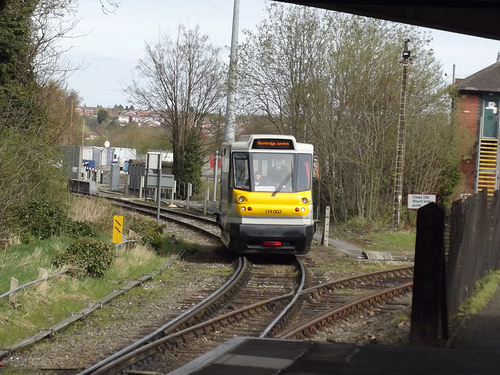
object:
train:
[215, 134, 317, 259]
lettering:
[257, 140, 289, 146]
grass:
[315, 257, 356, 275]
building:
[80, 144, 139, 175]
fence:
[386, 196, 498, 355]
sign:
[408, 194, 436, 210]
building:
[442, 64, 500, 179]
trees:
[254, 14, 417, 209]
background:
[72, 52, 336, 190]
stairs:
[473, 135, 497, 207]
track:
[201, 171, 291, 372]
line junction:
[217, 282, 332, 341]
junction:
[162, 256, 295, 360]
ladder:
[390, 40, 415, 228]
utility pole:
[393, 58, 407, 226]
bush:
[429, 168, 461, 198]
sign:
[257, 141, 290, 146]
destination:
[257, 141, 289, 146]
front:
[234, 182, 324, 220]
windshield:
[234, 153, 313, 198]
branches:
[246, 4, 333, 123]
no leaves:
[257, 26, 297, 56]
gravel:
[307, 259, 347, 279]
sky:
[78, 27, 149, 69]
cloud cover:
[73, 14, 191, 35]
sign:
[112, 215, 123, 244]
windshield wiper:
[271, 173, 292, 197]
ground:
[147, 257, 369, 344]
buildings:
[140, 149, 186, 196]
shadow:
[155, 233, 236, 265]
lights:
[240, 206, 246, 211]